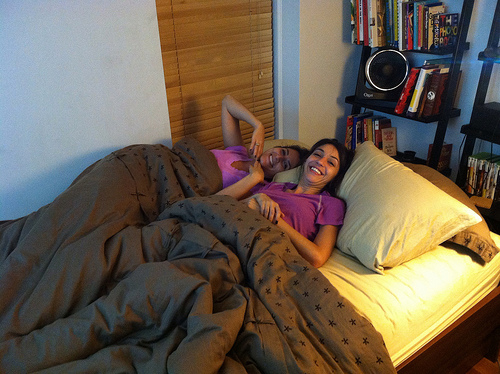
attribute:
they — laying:
[185, 82, 364, 267]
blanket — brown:
[0, 132, 400, 372]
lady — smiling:
[248, 140, 348, 266]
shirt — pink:
[207, 140, 264, 185]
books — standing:
[338, 0, 466, 62]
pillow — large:
[341, 144, 448, 253]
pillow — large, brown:
[335, 140, 485, 270]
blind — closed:
[155, 0, 285, 150]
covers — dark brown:
[3, 137, 351, 371]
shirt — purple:
[254, 181, 346, 236]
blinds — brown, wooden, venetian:
[162, 0, 270, 97]